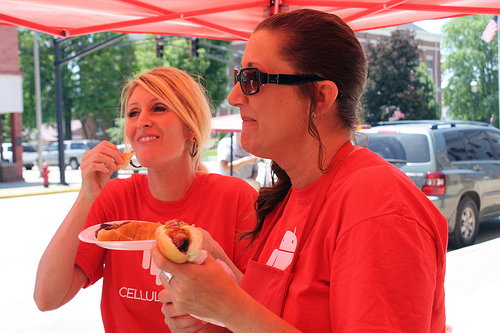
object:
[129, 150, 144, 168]
earring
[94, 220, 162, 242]
hot dog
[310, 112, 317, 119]
earring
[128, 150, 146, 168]
round earring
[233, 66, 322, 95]
sunglasses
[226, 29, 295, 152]
face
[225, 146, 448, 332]
shirt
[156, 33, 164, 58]
traffic light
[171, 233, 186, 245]
wiener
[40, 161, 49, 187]
fire hydrant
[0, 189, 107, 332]
street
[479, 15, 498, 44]
american flag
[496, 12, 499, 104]
flag pole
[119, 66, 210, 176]
hair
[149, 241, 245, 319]
hand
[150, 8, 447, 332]
woman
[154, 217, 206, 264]
hot dog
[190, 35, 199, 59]
street light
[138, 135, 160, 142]
teeth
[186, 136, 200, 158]
hooped earing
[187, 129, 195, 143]
ear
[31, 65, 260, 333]
woman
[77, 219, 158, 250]
plate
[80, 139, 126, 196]
hand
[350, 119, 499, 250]
suv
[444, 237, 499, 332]
curb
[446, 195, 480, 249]
back wheel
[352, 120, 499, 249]
car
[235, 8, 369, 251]
hair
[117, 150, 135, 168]
chip